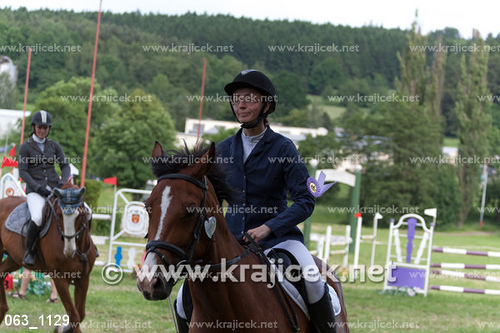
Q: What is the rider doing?
A: Riding a horse.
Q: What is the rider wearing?
A: A helmet.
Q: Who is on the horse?
A: A rider.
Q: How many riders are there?
A: Two.